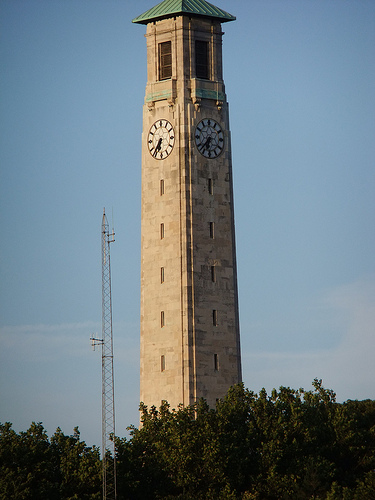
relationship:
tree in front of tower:
[108, 376, 374, 499] [131, 0, 242, 421]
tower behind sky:
[131, 0, 242, 421] [0, 1, 372, 459]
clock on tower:
[148, 118, 176, 159] [130, 2, 236, 393]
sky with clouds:
[260, 17, 371, 166] [253, 345, 373, 374]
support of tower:
[89, 336, 102, 349] [97, 205, 116, 495]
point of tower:
[101, 206, 106, 215] [99, 213, 118, 499]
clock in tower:
[148, 118, 175, 160] [114, 4, 250, 421]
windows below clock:
[205, 175, 214, 195] [193, 116, 226, 158]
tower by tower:
[89, 201, 130, 449] [114, 4, 250, 421]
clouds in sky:
[2, 315, 136, 369] [19, 54, 95, 285]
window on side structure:
[158, 177, 167, 193] [132, 5, 242, 429]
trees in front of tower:
[2, 376, 372, 493] [123, 6, 263, 323]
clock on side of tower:
[194, 118, 226, 159] [114, 4, 250, 421]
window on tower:
[155, 37, 176, 80] [115, 9, 286, 492]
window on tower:
[193, 26, 222, 89] [115, 9, 286, 492]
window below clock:
[155, 37, 176, 80] [190, 113, 235, 164]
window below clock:
[193, 36, 214, 79] [190, 113, 235, 164]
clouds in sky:
[253, 262, 373, 387] [264, 121, 340, 206]